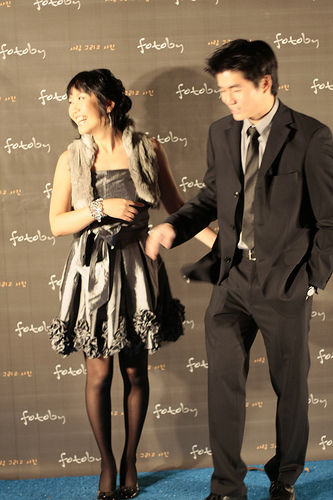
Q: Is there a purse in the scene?
A: No, there are no purses.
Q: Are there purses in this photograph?
A: No, there are no purses.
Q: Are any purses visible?
A: No, there are no purses.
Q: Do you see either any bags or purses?
A: No, there are no purses or bags.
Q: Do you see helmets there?
A: No, there are no helmets.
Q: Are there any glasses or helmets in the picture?
A: No, there are no helmets or glasses.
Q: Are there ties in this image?
A: Yes, there is a tie.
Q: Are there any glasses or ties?
A: Yes, there is a tie.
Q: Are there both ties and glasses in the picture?
A: No, there is a tie but no glasses.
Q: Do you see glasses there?
A: No, there are no glasses.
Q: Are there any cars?
A: No, there are no cars.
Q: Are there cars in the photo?
A: No, there are no cars.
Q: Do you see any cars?
A: No, there are no cars.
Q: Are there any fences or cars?
A: No, there are no cars or fences.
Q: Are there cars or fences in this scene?
A: No, there are no cars or fences.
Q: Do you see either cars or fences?
A: No, there are no cars or fences.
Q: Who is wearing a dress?
A: The people are wearing a dress.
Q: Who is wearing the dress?
A: The people are wearing a dress.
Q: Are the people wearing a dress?
A: Yes, the people are wearing a dress.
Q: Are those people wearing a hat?
A: No, the people are wearing a dress.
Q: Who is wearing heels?
A: The people are wearing heels.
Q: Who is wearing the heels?
A: The people are wearing heels.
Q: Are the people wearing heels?
A: Yes, the people are wearing heels.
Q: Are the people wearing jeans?
A: No, the people are wearing heels.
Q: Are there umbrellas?
A: No, there are no umbrellas.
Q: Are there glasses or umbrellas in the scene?
A: No, there are no umbrellas or glasses.